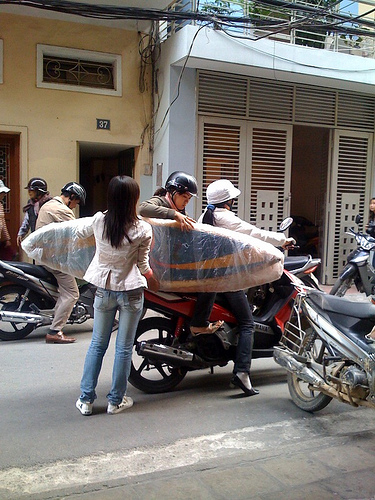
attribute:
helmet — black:
[61, 177, 91, 202]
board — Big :
[18, 212, 283, 295]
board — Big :
[25, 230, 261, 295]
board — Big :
[33, 211, 286, 303]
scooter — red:
[85, 188, 337, 417]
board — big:
[23, 213, 213, 277]